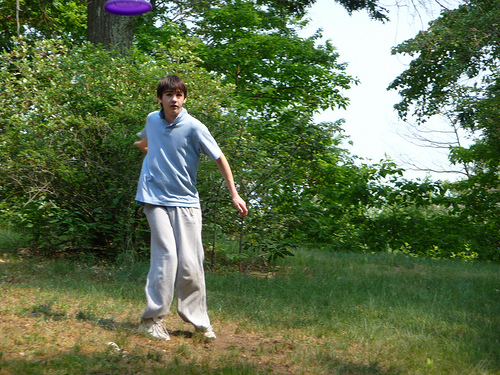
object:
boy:
[133, 76, 249, 343]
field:
[1, 244, 500, 374]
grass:
[0, 245, 500, 373]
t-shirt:
[134, 107, 224, 210]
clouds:
[285, 0, 500, 187]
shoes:
[196, 327, 217, 342]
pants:
[141, 206, 213, 330]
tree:
[386, 0, 499, 260]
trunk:
[85, 0, 135, 56]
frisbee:
[103, 0, 154, 15]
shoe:
[134, 319, 172, 340]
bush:
[1, 0, 500, 276]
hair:
[155, 75, 189, 100]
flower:
[57, 43, 66, 52]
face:
[161, 88, 185, 114]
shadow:
[29, 303, 194, 338]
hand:
[232, 194, 249, 216]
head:
[155, 74, 188, 114]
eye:
[175, 93, 183, 100]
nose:
[171, 96, 178, 104]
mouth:
[168, 102, 178, 109]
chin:
[170, 109, 181, 116]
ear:
[154, 94, 163, 105]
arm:
[192, 123, 238, 197]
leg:
[144, 205, 178, 321]